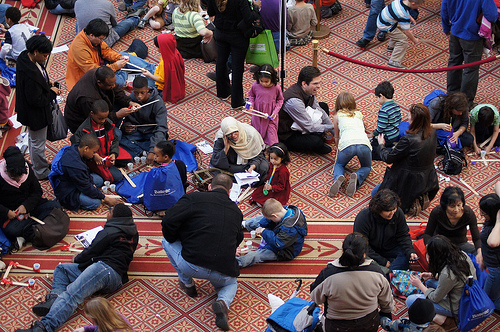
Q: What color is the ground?
A: Red and white.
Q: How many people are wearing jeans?
A: Six.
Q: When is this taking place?
A: Daytime.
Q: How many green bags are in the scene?
A: One.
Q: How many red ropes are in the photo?
A: One.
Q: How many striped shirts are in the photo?
A: Three.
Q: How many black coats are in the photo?
A: Six.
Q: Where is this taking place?
A: In the cafeteria.